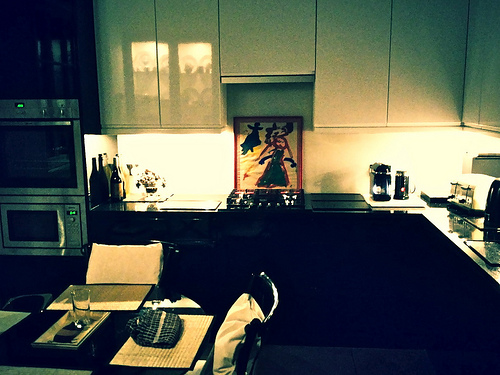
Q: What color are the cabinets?
A: White.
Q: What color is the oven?
A: Silver.